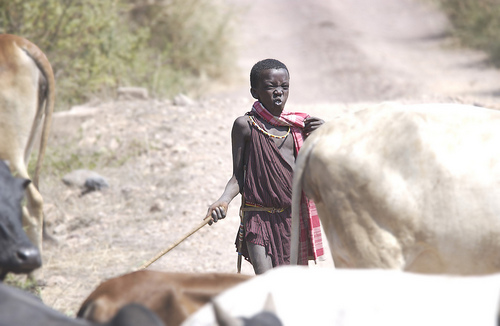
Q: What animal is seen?
A: Cow.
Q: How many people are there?
A: 1.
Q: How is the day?
A: Sunny.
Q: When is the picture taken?
A: Daytime.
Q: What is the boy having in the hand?
A: Stick.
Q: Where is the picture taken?
A: In Africa.